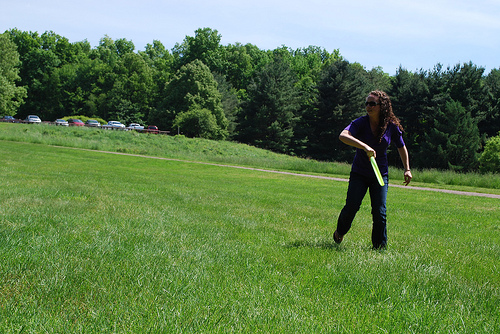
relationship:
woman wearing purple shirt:
[333, 90, 412, 250] [343, 113, 405, 176]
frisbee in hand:
[365, 149, 387, 187] [401, 168, 415, 188]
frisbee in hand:
[365, 149, 387, 187] [365, 148, 379, 160]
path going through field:
[4, 137, 498, 199] [9, 19, 499, 316]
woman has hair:
[333, 90, 412, 250] [367, 85, 406, 142]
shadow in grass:
[281, 233, 348, 253] [0, 122, 497, 332]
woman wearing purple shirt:
[333, 90, 412, 250] [349, 113, 396, 168]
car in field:
[128, 122, 143, 132] [0, 110, 178, 133]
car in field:
[107, 117, 124, 129] [0, 110, 178, 133]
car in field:
[85, 117, 102, 123] [0, 110, 178, 133]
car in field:
[67, 116, 88, 126] [1, 119, 495, 330]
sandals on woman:
[327, 226, 347, 258] [321, 78, 419, 272]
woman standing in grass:
[333, 90, 412, 250] [0, 122, 497, 332]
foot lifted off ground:
[328, 224, 346, 246] [5, 122, 499, 332]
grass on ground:
[0, 122, 497, 332] [5, 122, 499, 332]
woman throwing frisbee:
[333, 90, 412, 250] [365, 144, 388, 189]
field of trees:
[1, 119, 495, 330] [1, 25, 499, 175]